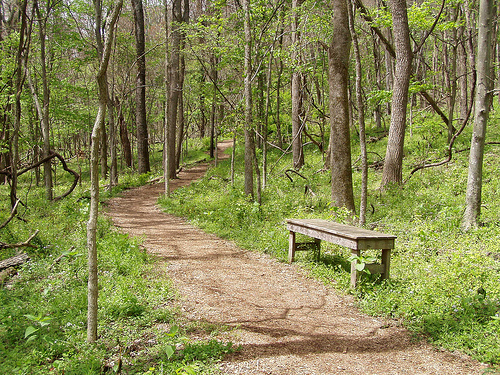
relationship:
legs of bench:
[284, 216, 399, 293] [285, 232, 320, 266]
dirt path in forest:
[101, 149, 490, 374] [51, 8, 374, 366]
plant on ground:
[19, 309, 61, 360] [0, 138, 499, 373]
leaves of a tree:
[0, 0, 498, 152] [85, 3, 124, 343]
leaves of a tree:
[0, 0, 498, 152] [389, 0, 415, 191]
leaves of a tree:
[0, 0, 498, 152] [329, 0, 357, 212]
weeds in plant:
[344, 250, 381, 280] [19, 309, 61, 360]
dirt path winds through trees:
[101, 149, 490, 374] [165, 18, 498, 232]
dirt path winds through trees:
[101, 149, 490, 374] [1, 16, 162, 343]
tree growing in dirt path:
[155, 5, 184, 209] [101, 149, 490, 374]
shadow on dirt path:
[212, 317, 427, 361] [101, 149, 490, 374]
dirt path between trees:
[101, 149, 490, 374] [70, 16, 114, 342]